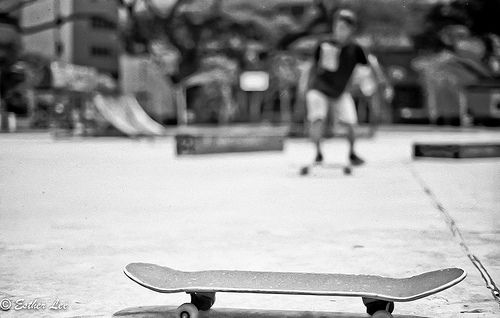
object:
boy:
[295, 5, 396, 164]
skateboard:
[118, 261, 468, 315]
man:
[306, 17, 386, 170]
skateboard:
[295, 157, 361, 178]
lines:
[408, 165, 500, 305]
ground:
[152, 196, 412, 259]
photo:
[5, 4, 499, 312]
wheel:
[369, 310, 389, 318]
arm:
[273, 38, 315, 60]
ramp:
[417, 136, 497, 162]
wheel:
[171, 304, 201, 318]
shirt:
[306, 36, 371, 99]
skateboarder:
[291, 7, 377, 170]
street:
[6, 121, 423, 306]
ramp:
[35, 55, 228, 143]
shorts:
[306, 92, 355, 124]